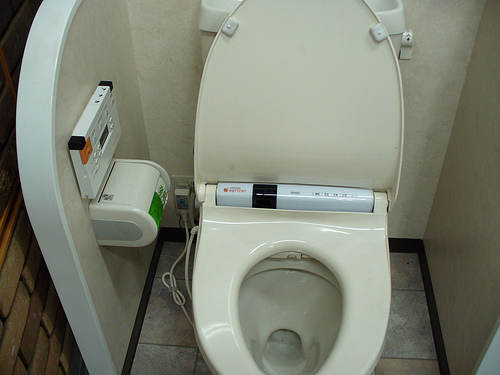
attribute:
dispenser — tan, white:
[94, 179, 169, 242]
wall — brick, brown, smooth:
[113, 28, 189, 74]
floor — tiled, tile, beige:
[149, 330, 184, 358]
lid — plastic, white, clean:
[276, 17, 384, 43]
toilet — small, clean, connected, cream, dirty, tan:
[173, 180, 381, 353]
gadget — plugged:
[186, 229, 196, 242]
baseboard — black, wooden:
[391, 242, 431, 273]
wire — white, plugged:
[162, 276, 185, 315]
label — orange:
[75, 144, 97, 162]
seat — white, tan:
[188, 204, 345, 255]